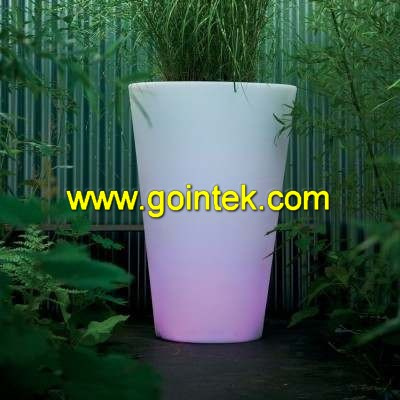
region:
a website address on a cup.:
[58, 171, 336, 220]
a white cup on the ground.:
[124, 82, 306, 344]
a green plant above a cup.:
[121, 0, 272, 76]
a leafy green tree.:
[0, 222, 62, 326]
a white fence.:
[9, 4, 398, 272]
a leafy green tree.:
[266, 1, 396, 227]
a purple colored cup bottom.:
[140, 235, 274, 351]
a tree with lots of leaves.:
[0, 219, 58, 296]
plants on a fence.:
[0, 22, 72, 83]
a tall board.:
[78, 110, 119, 202]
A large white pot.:
[126, 70, 300, 350]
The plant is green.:
[132, 1, 287, 354]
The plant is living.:
[123, 1, 302, 347]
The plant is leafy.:
[120, 0, 306, 358]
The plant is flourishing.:
[114, 2, 310, 360]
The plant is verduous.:
[118, 0, 300, 353]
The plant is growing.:
[115, 0, 304, 351]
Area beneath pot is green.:
[2, 310, 399, 398]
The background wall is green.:
[2, 1, 399, 321]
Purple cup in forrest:
[131, 74, 288, 340]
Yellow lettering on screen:
[67, 188, 331, 213]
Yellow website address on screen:
[66, 189, 334, 210]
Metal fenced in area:
[42, 62, 134, 199]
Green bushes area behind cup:
[146, 5, 263, 81]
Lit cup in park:
[125, 80, 294, 344]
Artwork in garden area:
[130, 82, 295, 347]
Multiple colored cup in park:
[131, 77, 298, 343]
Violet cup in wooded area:
[128, 78, 298, 343]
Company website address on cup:
[68, 183, 333, 215]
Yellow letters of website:
[59, 163, 343, 232]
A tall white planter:
[120, 67, 310, 351]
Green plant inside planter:
[130, 0, 296, 118]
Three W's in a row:
[65, 180, 138, 218]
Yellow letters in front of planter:
[60, 175, 333, 235]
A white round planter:
[113, 69, 290, 361]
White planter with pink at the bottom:
[102, 75, 312, 359]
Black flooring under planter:
[71, 311, 367, 393]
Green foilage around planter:
[4, 184, 175, 380]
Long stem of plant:
[326, 11, 399, 241]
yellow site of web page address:
[63, 173, 332, 223]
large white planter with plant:
[139, 87, 273, 180]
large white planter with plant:
[153, 229, 253, 332]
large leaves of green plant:
[4, 291, 121, 389]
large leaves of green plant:
[17, 209, 89, 283]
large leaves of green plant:
[0, 9, 100, 105]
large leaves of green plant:
[143, 13, 262, 65]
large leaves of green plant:
[316, 22, 378, 119]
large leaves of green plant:
[334, 132, 396, 258]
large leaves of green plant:
[284, 242, 388, 343]